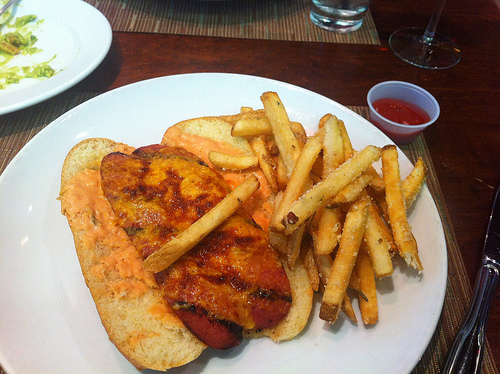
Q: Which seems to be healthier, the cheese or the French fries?
A: The cheese is healthier than the French fries.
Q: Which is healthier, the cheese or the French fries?
A: The cheese is healthier than the French fries.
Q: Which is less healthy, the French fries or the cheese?
A: The French fries is less healthy than the cheese.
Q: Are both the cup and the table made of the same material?
A: No, the cup is made of plastic and the table is made of wood.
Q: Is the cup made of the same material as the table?
A: No, the cup is made of plastic and the table is made of wood.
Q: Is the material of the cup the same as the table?
A: No, the cup is made of plastic and the table is made of wood.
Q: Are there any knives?
A: Yes, there is a knife.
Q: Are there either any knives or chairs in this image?
A: Yes, there is a knife.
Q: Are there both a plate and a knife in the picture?
A: Yes, there are both a knife and a plate.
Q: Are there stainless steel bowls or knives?
A: Yes, there is a stainless steel knife.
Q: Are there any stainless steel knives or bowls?
A: Yes, there is a stainless steel knife.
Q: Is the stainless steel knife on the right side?
A: Yes, the knife is on the right of the image.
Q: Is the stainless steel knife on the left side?
A: No, the knife is on the right of the image.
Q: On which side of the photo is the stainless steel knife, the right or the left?
A: The knife is on the right of the image.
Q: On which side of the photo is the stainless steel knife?
A: The knife is on the right of the image.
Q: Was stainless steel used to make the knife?
A: Yes, the knife is made of stainless steel.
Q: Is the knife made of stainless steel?
A: Yes, the knife is made of stainless steel.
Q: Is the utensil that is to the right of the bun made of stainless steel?
A: Yes, the knife is made of stainless steel.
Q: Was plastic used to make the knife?
A: No, the knife is made of stainless steel.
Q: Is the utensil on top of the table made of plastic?
A: No, the knife is made of stainless steel.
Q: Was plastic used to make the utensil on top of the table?
A: No, the knife is made of stainless steel.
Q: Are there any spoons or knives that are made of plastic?
A: No, there is a knife but it is made of stainless steel.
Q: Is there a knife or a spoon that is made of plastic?
A: No, there is a knife but it is made of stainless steel.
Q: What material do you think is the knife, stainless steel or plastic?
A: The knife is made of stainless steel.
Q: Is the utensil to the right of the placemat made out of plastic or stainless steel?
A: The knife is made of stainless steel.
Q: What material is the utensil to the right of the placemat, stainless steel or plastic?
A: The knife is made of stainless steel.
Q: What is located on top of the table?
A: The knife is on top of the table.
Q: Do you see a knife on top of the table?
A: Yes, there is a knife on top of the table.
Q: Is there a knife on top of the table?
A: Yes, there is a knife on top of the table.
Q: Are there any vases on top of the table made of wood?
A: No, there is a knife on top of the table.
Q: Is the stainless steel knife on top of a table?
A: Yes, the knife is on top of a table.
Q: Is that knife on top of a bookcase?
A: No, the knife is on top of a table.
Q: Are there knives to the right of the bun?
A: Yes, there is a knife to the right of the bun.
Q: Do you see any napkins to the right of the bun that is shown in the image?
A: No, there is a knife to the right of the bun.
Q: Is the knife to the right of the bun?
A: Yes, the knife is to the right of the bun.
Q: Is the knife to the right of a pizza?
A: No, the knife is to the right of the bun.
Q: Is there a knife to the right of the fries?
A: Yes, there is a knife to the right of the fries.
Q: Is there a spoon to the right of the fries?
A: No, there is a knife to the right of the fries.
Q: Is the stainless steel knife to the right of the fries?
A: Yes, the knife is to the right of the fries.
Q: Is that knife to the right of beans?
A: No, the knife is to the right of the fries.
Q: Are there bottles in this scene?
A: No, there are no bottles.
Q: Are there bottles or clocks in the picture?
A: No, there are no bottles or clocks.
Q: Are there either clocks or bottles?
A: No, there are no bottles or clocks.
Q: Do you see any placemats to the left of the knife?
A: Yes, there is a placemat to the left of the knife.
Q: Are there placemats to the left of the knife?
A: Yes, there is a placemat to the left of the knife.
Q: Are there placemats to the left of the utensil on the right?
A: Yes, there is a placemat to the left of the knife.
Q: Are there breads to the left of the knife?
A: No, there is a placemat to the left of the knife.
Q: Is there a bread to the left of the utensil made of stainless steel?
A: No, there is a placemat to the left of the knife.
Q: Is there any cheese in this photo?
A: Yes, there is cheese.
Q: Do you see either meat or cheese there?
A: Yes, there is cheese.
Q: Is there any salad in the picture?
A: No, there is no salad.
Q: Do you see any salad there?
A: No, there is no salad.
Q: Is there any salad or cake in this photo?
A: No, there are no salad or cakes.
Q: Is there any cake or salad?
A: No, there are no salad or cakes.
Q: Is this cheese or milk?
A: This is cheese.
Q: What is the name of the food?
A: The food is fries.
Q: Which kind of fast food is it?
A: The food is fries.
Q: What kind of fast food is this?
A: These are fries.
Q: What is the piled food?
A: The food is fries.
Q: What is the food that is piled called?
A: The food is fries.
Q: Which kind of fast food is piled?
A: The fast food is fries.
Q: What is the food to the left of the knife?
A: The food is fries.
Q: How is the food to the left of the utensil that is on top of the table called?
A: The food is fries.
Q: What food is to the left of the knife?
A: The food is fries.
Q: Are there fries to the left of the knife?
A: Yes, there are fries to the left of the knife.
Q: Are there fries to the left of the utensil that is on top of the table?
A: Yes, there are fries to the left of the knife.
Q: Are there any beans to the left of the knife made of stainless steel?
A: No, there are fries to the left of the knife.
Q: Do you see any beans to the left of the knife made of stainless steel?
A: No, there are fries to the left of the knife.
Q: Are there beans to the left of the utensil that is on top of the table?
A: No, there are fries to the left of the knife.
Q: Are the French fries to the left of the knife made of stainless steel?
A: Yes, the French fries are to the left of the knife.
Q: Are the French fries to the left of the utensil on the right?
A: Yes, the French fries are to the left of the knife.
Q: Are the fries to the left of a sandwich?
A: No, the fries are to the left of the knife.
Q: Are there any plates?
A: Yes, there is a plate.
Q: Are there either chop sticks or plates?
A: Yes, there is a plate.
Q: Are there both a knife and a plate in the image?
A: Yes, there are both a plate and a knife.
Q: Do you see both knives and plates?
A: Yes, there are both a plate and knives.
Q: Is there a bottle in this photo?
A: No, there are no bottles.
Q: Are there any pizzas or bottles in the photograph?
A: No, there are no bottles or pizzas.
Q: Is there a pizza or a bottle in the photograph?
A: No, there are no bottles or pizzas.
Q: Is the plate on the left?
A: Yes, the plate is on the left of the image.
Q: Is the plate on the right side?
A: No, the plate is on the left of the image.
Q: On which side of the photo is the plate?
A: The plate is on the left of the image.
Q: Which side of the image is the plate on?
A: The plate is on the left of the image.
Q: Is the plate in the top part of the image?
A: Yes, the plate is in the top of the image.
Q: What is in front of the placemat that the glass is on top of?
A: The plate is in front of the placemat.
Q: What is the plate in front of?
A: The plate is in front of the placemat.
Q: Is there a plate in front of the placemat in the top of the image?
A: Yes, there is a plate in front of the place mat.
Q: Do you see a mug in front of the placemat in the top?
A: No, there is a plate in front of the placemat.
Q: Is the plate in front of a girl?
A: No, the plate is in front of the placemat.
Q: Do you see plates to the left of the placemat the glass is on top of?
A: Yes, there is a plate to the left of the placemat.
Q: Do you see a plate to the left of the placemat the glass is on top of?
A: Yes, there is a plate to the left of the placemat.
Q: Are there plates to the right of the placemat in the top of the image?
A: No, the plate is to the left of the place mat.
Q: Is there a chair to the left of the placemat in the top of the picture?
A: No, there is a plate to the left of the placemat.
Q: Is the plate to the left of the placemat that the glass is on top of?
A: Yes, the plate is to the left of the placemat.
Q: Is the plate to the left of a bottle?
A: No, the plate is to the left of the placemat.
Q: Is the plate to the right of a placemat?
A: No, the plate is to the left of a placemat.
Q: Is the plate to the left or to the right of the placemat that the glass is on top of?
A: The plate is to the left of the placemat.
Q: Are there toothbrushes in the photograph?
A: No, there are no toothbrushes.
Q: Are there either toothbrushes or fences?
A: No, there are no toothbrushes or fences.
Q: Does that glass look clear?
A: Yes, the glass is clear.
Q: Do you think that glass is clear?
A: Yes, the glass is clear.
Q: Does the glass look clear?
A: Yes, the glass is clear.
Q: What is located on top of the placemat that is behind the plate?
A: The glass is on top of the place mat.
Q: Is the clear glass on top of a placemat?
A: Yes, the glass is on top of a placemat.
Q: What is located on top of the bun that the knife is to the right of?
A: The sauce is on top of the bun.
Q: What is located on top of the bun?
A: The sauce is on top of the bun.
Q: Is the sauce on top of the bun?
A: Yes, the sauce is on top of the bun.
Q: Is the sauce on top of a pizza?
A: No, the sauce is on top of the bun.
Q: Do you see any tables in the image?
A: Yes, there is a table.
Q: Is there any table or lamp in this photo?
A: Yes, there is a table.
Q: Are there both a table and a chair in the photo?
A: No, there is a table but no chairs.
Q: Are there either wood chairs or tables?
A: Yes, there is a wood table.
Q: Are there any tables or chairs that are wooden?
A: Yes, the table is wooden.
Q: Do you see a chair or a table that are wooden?
A: Yes, the table is wooden.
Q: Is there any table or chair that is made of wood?
A: Yes, the table is made of wood.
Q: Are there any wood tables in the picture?
A: Yes, there is a table that is made of wood.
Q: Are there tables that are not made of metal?
A: Yes, there is a table that is made of wood.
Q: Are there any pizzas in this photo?
A: No, there are no pizzas.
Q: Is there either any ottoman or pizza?
A: No, there are no pizzas or ottomen.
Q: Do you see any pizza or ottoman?
A: No, there are no pizzas or ottomen.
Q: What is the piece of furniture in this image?
A: The piece of furniture is a table.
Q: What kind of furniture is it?
A: The piece of furniture is a table.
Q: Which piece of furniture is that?
A: This is a table.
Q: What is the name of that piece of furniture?
A: This is a table.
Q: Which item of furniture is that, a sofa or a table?
A: This is a table.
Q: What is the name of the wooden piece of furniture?
A: The piece of furniture is a table.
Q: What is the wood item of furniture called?
A: The piece of furniture is a table.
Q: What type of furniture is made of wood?
A: The furniture is a table.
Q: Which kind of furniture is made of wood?
A: The furniture is a table.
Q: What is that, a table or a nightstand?
A: That is a table.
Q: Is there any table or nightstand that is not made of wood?
A: No, there is a table but it is made of wood.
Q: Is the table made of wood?
A: Yes, the table is made of wood.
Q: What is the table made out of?
A: The table is made of wood.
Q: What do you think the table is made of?
A: The table is made of wood.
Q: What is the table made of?
A: The table is made of wood.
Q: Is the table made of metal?
A: No, the table is made of wood.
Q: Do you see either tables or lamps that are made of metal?
A: No, there is a table but it is made of wood.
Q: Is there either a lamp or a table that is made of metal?
A: No, there is a table but it is made of wood.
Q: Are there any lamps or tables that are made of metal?
A: No, there is a table but it is made of wood.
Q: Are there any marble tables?
A: No, there is a table but it is made of wood.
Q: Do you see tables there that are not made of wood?
A: No, there is a table but it is made of wood.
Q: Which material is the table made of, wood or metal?
A: The table is made of wood.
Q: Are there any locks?
A: No, there are no locks.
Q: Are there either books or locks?
A: No, there are no locks or books.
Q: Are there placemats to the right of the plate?
A: Yes, there is a placemat to the right of the plate.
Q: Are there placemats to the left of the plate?
A: No, the placemat is to the right of the plate.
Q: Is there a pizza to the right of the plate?
A: No, there is a placemat to the right of the plate.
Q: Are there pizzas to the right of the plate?
A: No, there is a placemat to the right of the plate.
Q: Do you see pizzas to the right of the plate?
A: No, there is a placemat to the right of the plate.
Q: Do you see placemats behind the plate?
A: Yes, there is a placemat behind the plate.